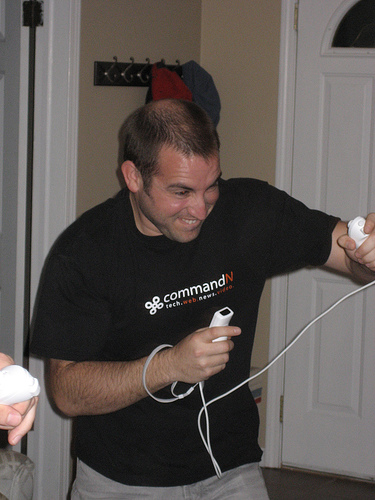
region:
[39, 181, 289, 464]
the t-shirt is black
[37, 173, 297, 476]
the t-shirt is black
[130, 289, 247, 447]
man is holding Wii controller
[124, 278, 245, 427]
man is holding Wii controller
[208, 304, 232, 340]
Wii controller in man's hand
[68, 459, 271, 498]
White pants on man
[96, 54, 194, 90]
Hooks on a wall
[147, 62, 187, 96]
Red cloth on a hook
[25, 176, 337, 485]
Black shirt on a man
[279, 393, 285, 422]
Metal hinge on a white door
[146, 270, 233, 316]
Words on a black shirt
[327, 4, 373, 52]
A window in a door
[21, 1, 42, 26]
Hinges on the side of a door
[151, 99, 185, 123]
Bald spot on a man's head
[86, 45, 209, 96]
black rack on the wall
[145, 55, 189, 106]
red baseball cap on the wall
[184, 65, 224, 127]
gray baseball cap on the wall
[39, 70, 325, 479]
man wearing black shirt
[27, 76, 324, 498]
man holding game controller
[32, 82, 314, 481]
man with thinning hair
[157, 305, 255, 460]
wii controller with strap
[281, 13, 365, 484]
white door with window on top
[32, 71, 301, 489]
man wearing gray jean pants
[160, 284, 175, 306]
white letter on shirt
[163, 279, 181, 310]
white letter on shirt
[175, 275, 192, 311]
white letter on shirt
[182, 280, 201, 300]
white letter on shirt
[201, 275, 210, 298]
white letter on shirt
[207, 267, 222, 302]
white letter on shirt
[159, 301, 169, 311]
white letter on shirt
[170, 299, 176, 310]
white letter on shirt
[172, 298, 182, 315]
white letter on shirt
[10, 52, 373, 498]
the is a man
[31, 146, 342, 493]
man wearing a black shirt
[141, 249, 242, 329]
white writing on shirt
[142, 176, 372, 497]
the remotes are white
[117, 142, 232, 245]
the man is grimacing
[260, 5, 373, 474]
white door in background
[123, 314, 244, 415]
chord on the wrist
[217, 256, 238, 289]
orange letter on shirt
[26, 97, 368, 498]
A man.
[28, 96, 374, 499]
A man playing a video game.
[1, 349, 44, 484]
The hand of a second person holding a remote.